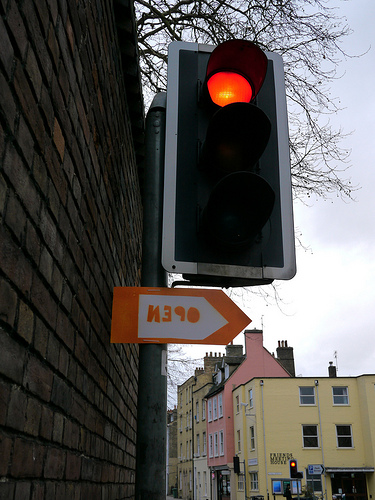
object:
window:
[248, 389, 253, 408]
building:
[328, 361, 336, 378]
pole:
[140, 92, 167, 287]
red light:
[208, 72, 258, 106]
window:
[250, 426, 256, 452]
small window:
[299, 385, 316, 406]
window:
[235, 428, 243, 452]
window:
[235, 395, 240, 414]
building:
[276, 340, 295, 377]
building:
[166, 409, 178, 496]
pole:
[135, 92, 167, 498]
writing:
[147, 305, 200, 323]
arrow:
[111, 287, 253, 345]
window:
[331, 386, 350, 407]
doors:
[325, 467, 371, 499]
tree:
[133, 1, 371, 411]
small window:
[301, 424, 320, 450]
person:
[283, 484, 292, 499]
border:
[161, 41, 197, 275]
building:
[204, 327, 293, 500]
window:
[207, 392, 223, 422]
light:
[207, 72, 252, 107]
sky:
[134, 0, 375, 411]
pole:
[135, 343, 167, 497]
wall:
[0, 5, 146, 500]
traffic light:
[289, 459, 304, 479]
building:
[232, 374, 375, 496]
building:
[177, 351, 225, 499]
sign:
[162, 39, 297, 288]